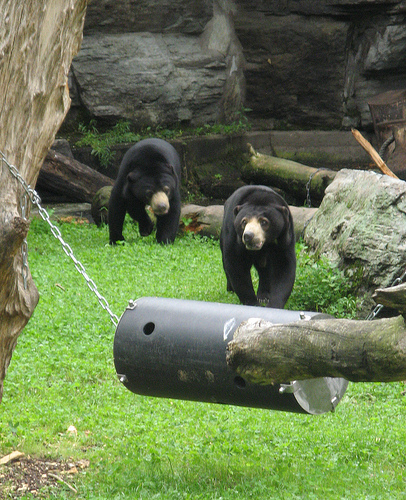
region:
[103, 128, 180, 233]
the bear is black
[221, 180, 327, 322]
the bear is black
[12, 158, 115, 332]
chain tied to a tree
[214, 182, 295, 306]
a brown bear walking around at the zoo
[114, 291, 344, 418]
a big can attached by some chains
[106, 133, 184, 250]
the other bear walking around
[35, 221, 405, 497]
the green grass on the ground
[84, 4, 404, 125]
the brick wall next behind the bears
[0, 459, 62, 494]
the pile of dirt on the ground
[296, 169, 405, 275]
a big rock next to the bear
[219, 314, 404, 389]
the tree branch next to the barrel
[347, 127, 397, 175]
another tree branch sticking out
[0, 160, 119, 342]
a long metal chain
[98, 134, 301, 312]
two bears walking on green grass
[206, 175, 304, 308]
one black bear walking across grass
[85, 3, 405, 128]
rock formation cave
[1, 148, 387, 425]
metal hanging tube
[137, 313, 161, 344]
black hole on metal cylinder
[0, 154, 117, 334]
metal chain attached to metal cylinder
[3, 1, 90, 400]
brown tree trunk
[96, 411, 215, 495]
patch of green grass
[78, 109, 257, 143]
green plants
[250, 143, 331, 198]
wooden log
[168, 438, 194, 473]
part of a ground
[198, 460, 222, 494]
part of a ground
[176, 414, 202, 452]
part of a ground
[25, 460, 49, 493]
part of a ground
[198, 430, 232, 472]
part of a ground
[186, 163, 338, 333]
bear in the grass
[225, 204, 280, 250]
head of the bear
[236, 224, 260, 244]
nose of the bear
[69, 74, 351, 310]
two bears next to each other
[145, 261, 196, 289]
grass on the ground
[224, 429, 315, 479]
grass in front of the bear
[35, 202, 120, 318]
chain next to the tree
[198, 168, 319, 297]
brown and black bear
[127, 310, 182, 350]
hole in the object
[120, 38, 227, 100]
rock in the background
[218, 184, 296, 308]
the black bear closer to the camera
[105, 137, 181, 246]
the black bear farther from the camera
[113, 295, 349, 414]
the cylindrical object hanging on chains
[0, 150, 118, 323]
the chain on the left from the cylindrical object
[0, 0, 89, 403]
the large tree trunk on the left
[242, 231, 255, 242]
the black nose of the bear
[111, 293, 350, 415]
Long circular black bear feeder.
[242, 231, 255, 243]
Black nose on a bear close to a feeder.